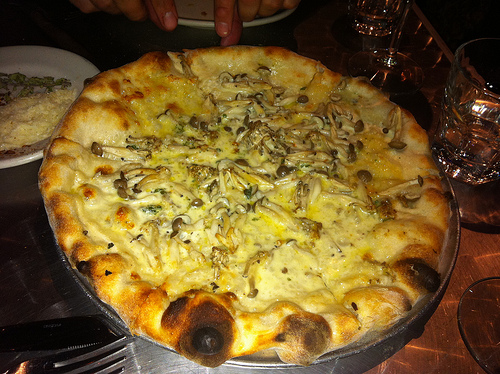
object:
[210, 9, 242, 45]
finger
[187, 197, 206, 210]
mushrooms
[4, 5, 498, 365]
countertop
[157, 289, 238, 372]
crust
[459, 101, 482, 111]
glass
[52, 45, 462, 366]
pan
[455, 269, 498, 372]
plate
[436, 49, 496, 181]
wine glass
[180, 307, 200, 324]
burnt spot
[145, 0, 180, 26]
fingers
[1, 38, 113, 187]
plate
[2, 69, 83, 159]
food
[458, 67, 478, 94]
glass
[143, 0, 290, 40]
plate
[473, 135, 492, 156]
glass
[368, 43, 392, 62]
glass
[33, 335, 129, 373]
fork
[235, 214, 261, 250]
cheese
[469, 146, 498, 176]
glass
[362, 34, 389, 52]
glass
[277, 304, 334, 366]
crust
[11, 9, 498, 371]
table top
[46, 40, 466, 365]
platter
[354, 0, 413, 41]
glasses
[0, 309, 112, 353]
butter knife